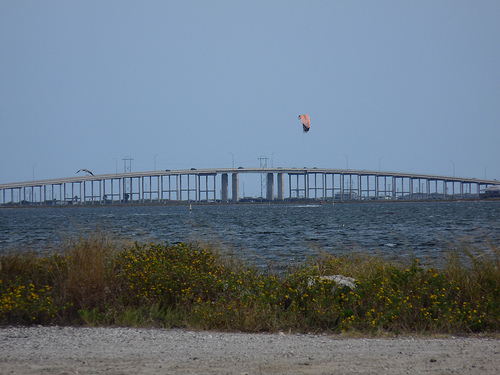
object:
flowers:
[107, 241, 291, 308]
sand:
[2, 326, 499, 375]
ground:
[2, 248, 495, 374]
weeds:
[205, 273, 434, 335]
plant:
[373, 259, 500, 333]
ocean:
[3, 196, 498, 260]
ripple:
[127, 203, 495, 214]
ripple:
[1, 213, 120, 242]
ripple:
[437, 228, 494, 256]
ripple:
[394, 216, 498, 234]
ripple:
[252, 235, 388, 249]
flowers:
[335, 265, 488, 331]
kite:
[298, 114, 311, 134]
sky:
[1, 1, 499, 196]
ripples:
[191, 210, 253, 229]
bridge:
[1, 165, 498, 205]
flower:
[17, 285, 26, 290]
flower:
[30, 290, 39, 299]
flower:
[9, 297, 13, 303]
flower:
[40, 291, 46, 296]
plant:
[3, 232, 264, 329]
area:
[0, 240, 497, 374]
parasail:
[297, 114, 310, 134]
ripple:
[256, 219, 368, 240]